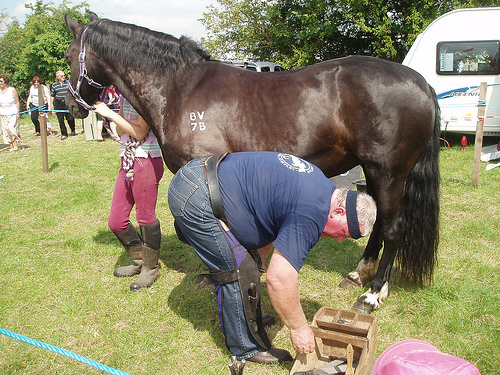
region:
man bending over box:
[167, 150, 378, 360]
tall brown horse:
[65, 7, 441, 316]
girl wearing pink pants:
[93, 90, 162, 291]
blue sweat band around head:
[345, 187, 361, 242]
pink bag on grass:
[370, 335, 478, 373]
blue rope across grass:
[0, 327, 126, 374]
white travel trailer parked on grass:
[402, 4, 498, 148]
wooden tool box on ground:
[287, 304, 377, 374]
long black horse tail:
[402, 85, 443, 289]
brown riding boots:
[110, 220, 163, 289]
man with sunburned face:
[320, 190, 368, 247]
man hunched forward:
[163, 148, 379, 368]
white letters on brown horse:
[188, 110, 210, 137]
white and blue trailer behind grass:
[392, 7, 499, 140]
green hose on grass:
[0, 320, 134, 374]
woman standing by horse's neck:
[98, 81, 164, 291]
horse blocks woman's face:
[84, 31, 169, 292]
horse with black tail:
[396, 80, 441, 292]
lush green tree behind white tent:
[196, 1, 498, 133]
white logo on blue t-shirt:
[272, 150, 315, 177]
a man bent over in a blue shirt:
[159, 146, 377, 361]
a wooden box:
[291, 306, 383, 373]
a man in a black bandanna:
[323, 189, 373, 240]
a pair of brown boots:
[105, 217, 161, 292]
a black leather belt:
[199, 153, 226, 213]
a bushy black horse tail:
[400, 76, 445, 286]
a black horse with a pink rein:
[56, 8, 106, 118]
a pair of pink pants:
[106, 155, 159, 238]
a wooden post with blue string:
[0, 95, 54, 165]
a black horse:
[54, 13, 457, 293]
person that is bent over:
[150, 163, 386, 340]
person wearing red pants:
[112, 150, 152, 227]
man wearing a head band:
[336, 188, 370, 254]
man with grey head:
[328, 186, 376, 237]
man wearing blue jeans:
[166, 160, 261, 360]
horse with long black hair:
[398, 89, 444, 269]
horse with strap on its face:
[58, 56, 105, 108]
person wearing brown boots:
[126, 213, 164, 293]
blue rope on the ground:
[1, 326, 111, 370]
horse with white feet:
[360, 280, 402, 305]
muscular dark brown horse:
[56, 8, 446, 318]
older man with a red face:
[158, 138, 387, 374]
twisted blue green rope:
[0, 317, 125, 374]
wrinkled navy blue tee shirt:
[195, 140, 337, 272]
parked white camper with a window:
[391, 9, 498, 143]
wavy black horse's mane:
[83, 13, 203, 80]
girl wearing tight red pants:
[92, 77, 168, 299]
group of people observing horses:
[0, 66, 121, 153]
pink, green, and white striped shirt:
[112, 93, 174, 167]